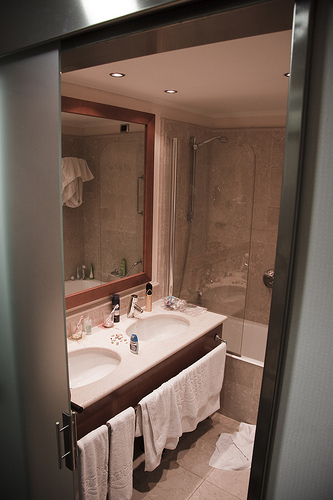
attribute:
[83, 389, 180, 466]
towels — white, hanging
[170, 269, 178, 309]
toothbrushes — white, pink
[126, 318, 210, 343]
sink — white, round, large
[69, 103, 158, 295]
mirror — large, framed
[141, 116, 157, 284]
frame — wood, brown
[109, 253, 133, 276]
body wash — green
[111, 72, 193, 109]
lights — small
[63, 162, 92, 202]
towel — white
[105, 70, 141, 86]
light — round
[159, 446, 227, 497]
tiles — tan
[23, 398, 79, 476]
door — silver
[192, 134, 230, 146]
shower head — long, silver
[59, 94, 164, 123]
edge — brown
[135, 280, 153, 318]
can — tan, brown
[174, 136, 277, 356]
shower — sliding, chrome, glass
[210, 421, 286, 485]
towel — wet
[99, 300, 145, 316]
faucet — silver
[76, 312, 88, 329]
toothbrushes — pink, white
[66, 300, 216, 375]
sinks — double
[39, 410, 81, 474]
door handle — metal